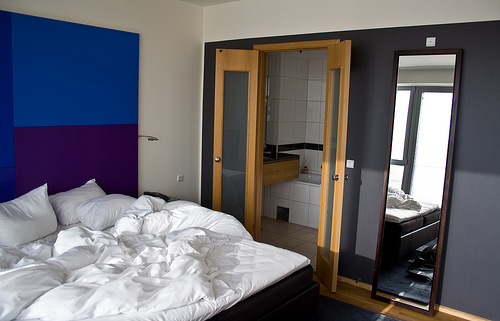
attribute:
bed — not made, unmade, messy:
[1, 179, 318, 320]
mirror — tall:
[371, 48, 459, 316]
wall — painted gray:
[338, 22, 499, 320]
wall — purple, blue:
[1, 8, 200, 204]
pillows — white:
[0, 177, 137, 256]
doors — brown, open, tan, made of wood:
[210, 36, 354, 293]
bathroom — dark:
[262, 50, 328, 270]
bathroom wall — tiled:
[267, 52, 327, 175]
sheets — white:
[0, 195, 253, 320]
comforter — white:
[1, 196, 248, 313]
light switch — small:
[345, 159, 356, 170]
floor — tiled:
[261, 217, 317, 271]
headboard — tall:
[2, 12, 137, 199]